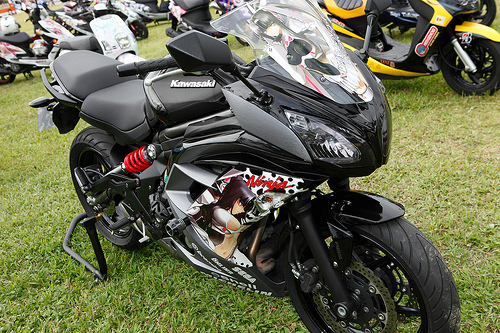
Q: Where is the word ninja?
A: On the motorcycle.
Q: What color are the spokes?
A: Black.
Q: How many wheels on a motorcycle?
A: Two.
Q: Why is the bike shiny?
A: It is new.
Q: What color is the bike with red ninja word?
A: Black.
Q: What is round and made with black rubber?
A: Tires.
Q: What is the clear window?
A: A shield.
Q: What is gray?
A: The seats.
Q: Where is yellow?
A: On the motorcycle.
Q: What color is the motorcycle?
A: Black.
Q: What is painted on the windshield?
A: Girl.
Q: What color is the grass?
A: Green.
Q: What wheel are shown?
A: Front.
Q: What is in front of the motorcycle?
A: Handlebar.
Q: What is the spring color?
A: Red.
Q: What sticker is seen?
A: Animal mouth.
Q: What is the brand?
A: Kawasaki.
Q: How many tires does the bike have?
A: Two.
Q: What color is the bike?
A: Black.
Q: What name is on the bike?
A: Kawasaki.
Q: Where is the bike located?
A: On the grass.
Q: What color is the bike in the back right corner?
A: Yellow.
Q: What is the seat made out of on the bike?
A: Leather.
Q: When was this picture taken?
A: In the daytime.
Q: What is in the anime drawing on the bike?
A: A girl.